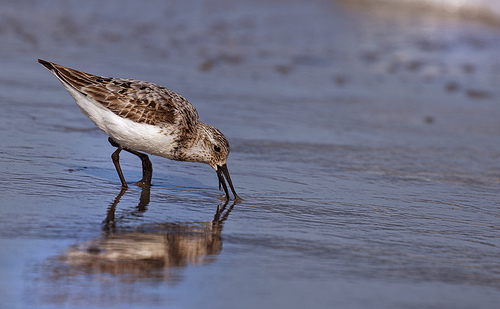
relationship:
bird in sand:
[40, 49, 248, 209] [247, 249, 303, 287]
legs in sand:
[94, 158, 160, 192] [247, 249, 303, 287]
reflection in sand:
[65, 230, 226, 280] [247, 249, 303, 287]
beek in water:
[199, 163, 242, 207] [374, 126, 422, 168]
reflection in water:
[65, 230, 226, 280] [374, 126, 422, 168]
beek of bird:
[214, 163, 242, 204] [40, 49, 248, 209]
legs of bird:
[94, 158, 160, 192] [40, 49, 248, 209]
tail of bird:
[48, 48, 88, 98] [40, 49, 248, 209]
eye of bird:
[207, 140, 230, 170] [40, 49, 248, 209]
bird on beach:
[40, 49, 248, 209] [247, 249, 303, 287]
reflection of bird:
[65, 230, 226, 280] [40, 49, 248, 209]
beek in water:
[214, 163, 242, 204] [374, 126, 422, 168]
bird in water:
[40, 49, 248, 209] [374, 126, 422, 168]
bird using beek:
[40, 49, 248, 209] [214, 163, 242, 204]